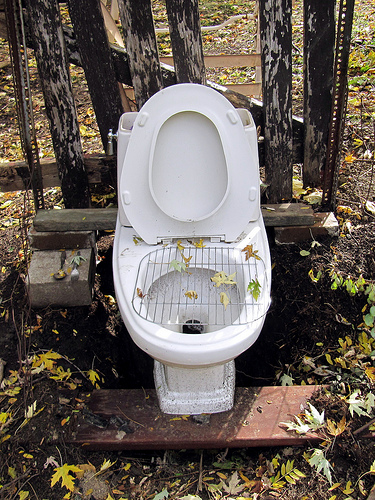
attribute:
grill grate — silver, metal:
[131, 245, 273, 326]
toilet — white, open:
[106, 82, 273, 417]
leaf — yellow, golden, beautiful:
[46, 447, 83, 494]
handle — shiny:
[105, 125, 117, 157]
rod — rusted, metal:
[317, 2, 355, 211]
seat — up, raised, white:
[120, 83, 249, 243]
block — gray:
[24, 246, 97, 308]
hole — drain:
[182, 318, 203, 335]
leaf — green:
[70, 256, 86, 265]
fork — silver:
[69, 249, 83, 283]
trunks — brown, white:
[24, 0, 336, 208]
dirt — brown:
[32, 242, 364, 387]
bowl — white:
[112, 227, 273, 368]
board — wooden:
[73, 384, 331, 451]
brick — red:
[275, 208, 338, 244]